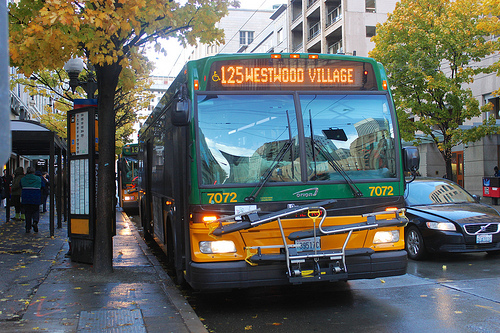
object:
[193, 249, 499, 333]
road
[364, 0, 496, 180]
tree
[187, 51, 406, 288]
front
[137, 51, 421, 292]
bus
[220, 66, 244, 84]
number 125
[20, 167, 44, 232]
man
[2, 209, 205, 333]
sidewalk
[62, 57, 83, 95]
street light